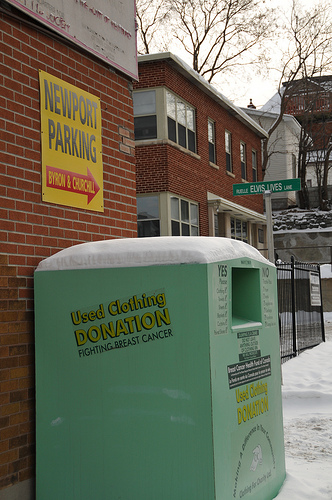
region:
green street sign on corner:
[235, 180, 302, 195]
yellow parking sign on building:
[43, 75, 107, 215]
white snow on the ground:
[283, 357, 328, 397]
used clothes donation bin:
[44, 242, 277, 496]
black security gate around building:
[288, 260, 309, 351]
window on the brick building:
[135, 87, 161, 142]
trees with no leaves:
[181, 3, 313, 57]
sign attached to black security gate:
[312, 271, 321, 308]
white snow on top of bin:
[70, 243, 225, 262]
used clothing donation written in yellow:
[73, 281, 170, 344]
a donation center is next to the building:
[33, 232, 272, 495]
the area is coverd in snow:
[291, 353, 324, 489]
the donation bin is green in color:
[30, 252, 300, 497]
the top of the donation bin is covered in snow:
[41, 233, 283, 277]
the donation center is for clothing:
[61, 288, 178, 344]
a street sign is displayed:
[232, 173, 302, 202]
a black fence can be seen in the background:
[279, 256, 323, 362]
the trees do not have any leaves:
[139, 5, 316, 86]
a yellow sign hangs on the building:
[29, 66, 115, 215]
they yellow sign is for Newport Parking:
[32, 68, 116, 214]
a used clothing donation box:
[33, 232, 297, 495]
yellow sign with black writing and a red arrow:
[33, 63, 111, 218]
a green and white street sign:
[228, 179, 301, 198]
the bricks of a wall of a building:
[2, 93, 33, 151]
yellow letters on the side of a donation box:
[60, 297, 181, 339]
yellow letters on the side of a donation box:
[233, 379, 271, 425]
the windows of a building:
[163, 86, 201, 159]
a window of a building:
[204, 112, 220, 169]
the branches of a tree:
[181, 6, 242, 56]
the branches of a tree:
[289, 16, 324, 79]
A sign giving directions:
[37, 67, 107, 212]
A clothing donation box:
[39, 246, 276, 497]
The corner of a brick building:
[0, 0, 137, 498]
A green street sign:
[230, 181, 300, 193]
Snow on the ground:
[262, 307, 330, 498]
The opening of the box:
[226, 267, 265, 328]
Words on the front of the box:
[215, 331, 280, 487]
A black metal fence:
[273, 257, 327, 360]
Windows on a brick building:
[136, 87, 257, 189]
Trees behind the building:
[139, 0, 327, 208]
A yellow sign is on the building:
[23, 61, 145, 227]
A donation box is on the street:
[30, 236, 327, 498]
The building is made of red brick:
[144, 142, 241, 235]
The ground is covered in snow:
[277, 347, 322, 485]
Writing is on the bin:
[56, 286, 229, 389]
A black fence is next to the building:
[252, 248, 329, 313]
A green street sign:
[227, 173, 313, 222]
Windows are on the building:
[130, 78, 221, 208]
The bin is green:
[34, 244, 319, 434]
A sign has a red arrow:
[34, 145, 118, 205]